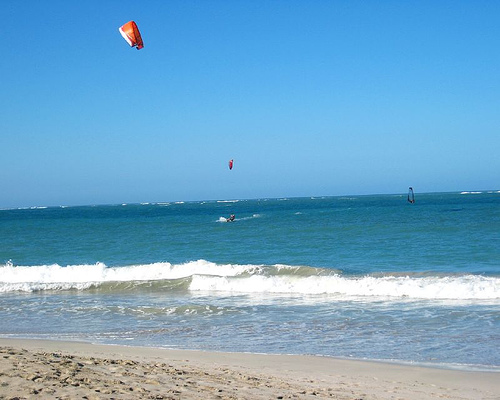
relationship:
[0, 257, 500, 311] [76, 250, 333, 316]
wave are crashing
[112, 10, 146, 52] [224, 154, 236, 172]
kite used for kitesurfing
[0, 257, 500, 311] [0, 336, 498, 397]
wave breaking on beach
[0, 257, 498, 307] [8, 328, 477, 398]
wave on beach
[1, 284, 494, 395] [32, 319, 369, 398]
beach on coast line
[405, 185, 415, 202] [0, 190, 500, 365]
bouey in blue water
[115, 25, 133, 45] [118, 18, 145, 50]
stripe on kite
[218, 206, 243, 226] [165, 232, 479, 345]
kite surfer on water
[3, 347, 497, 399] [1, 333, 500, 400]
tracks in beach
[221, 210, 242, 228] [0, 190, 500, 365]
man are wakeboarding in blue water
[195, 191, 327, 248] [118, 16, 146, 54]
man using parasail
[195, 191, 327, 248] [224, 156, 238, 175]
man with background parasail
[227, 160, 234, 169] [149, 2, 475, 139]
parasail and sky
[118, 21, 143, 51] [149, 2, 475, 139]
parasail and sky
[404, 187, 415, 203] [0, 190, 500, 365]
vessel on blue water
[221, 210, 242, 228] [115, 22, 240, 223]
man enjoying kitesurfing